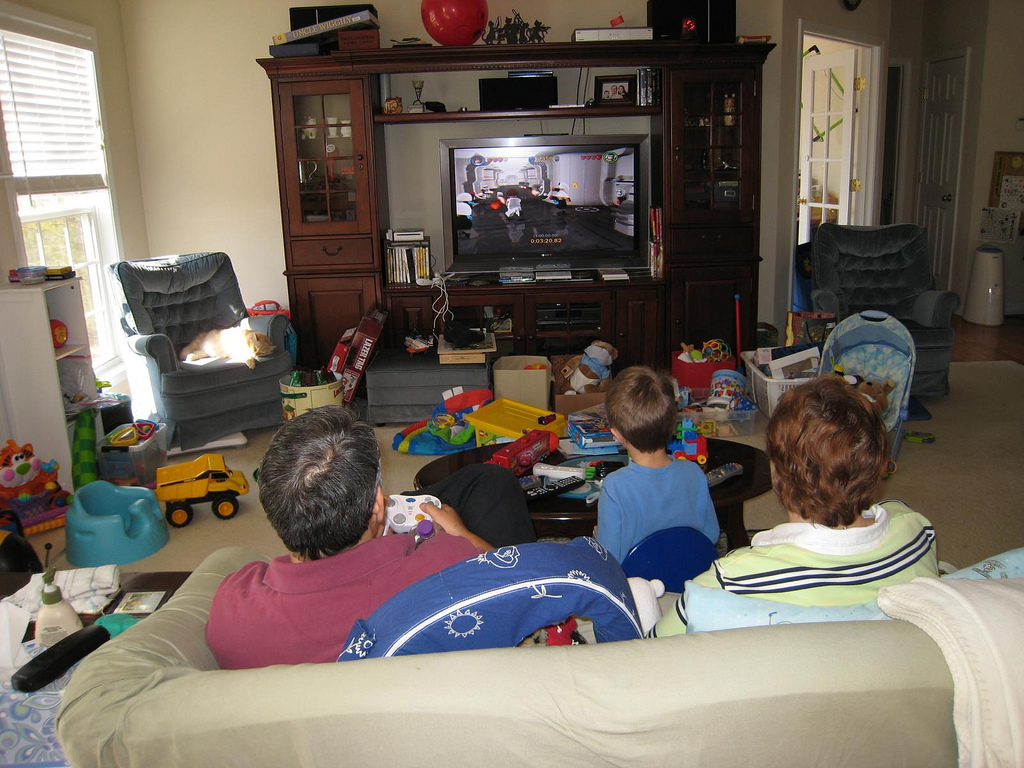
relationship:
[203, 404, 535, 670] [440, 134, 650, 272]
man playing entertainment center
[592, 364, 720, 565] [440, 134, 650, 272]
boy playing entertainment center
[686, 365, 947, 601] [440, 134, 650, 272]
person playing entertainment center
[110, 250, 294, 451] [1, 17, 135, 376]
chair by window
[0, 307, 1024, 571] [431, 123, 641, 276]
floor by tv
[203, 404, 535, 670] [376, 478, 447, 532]
man holding game controller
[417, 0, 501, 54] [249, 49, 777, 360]
red ball on shelf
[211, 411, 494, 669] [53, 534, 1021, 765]
man sitting on couch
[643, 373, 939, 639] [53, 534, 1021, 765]
person sitting on couch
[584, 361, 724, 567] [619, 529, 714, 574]
boy sitting in chair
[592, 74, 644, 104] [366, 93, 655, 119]
picture on shelf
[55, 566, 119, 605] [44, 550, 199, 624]
towel on table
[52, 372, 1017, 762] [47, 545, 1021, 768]
people sitting on couch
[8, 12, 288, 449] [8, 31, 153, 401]
chair near window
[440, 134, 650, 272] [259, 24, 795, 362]
entertainment center in entertainment center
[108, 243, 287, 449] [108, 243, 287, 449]
cat on chair